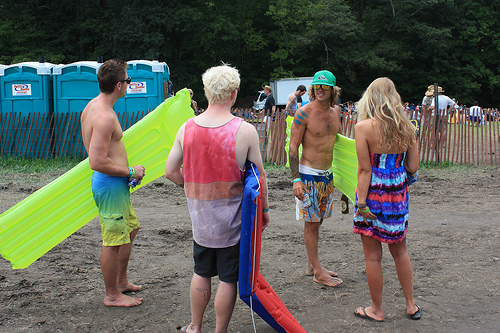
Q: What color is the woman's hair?
A: Blonde.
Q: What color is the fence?
A: Brown.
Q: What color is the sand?
A: Brown.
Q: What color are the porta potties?
A: Blue.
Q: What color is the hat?
A: Green.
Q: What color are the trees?
A: Green.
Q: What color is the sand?
A: Brown.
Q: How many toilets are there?
A: Three.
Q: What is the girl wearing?
A: A dress.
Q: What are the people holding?
A: Pool toys.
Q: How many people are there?
A: More than five.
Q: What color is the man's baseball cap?
A: Green.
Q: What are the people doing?
A: Talking.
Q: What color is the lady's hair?
A: Blonde.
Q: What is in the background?
A: Trees.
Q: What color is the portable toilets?
A: Blue.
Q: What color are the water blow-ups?
A: Yellow.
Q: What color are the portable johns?
A: Blue.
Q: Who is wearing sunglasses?
A: The men.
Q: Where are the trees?
A: Behind the fence.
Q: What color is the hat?
A: Teal.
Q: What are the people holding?
A: Air mattresses.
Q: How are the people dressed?
A: To go to the beach.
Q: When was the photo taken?
A: During the day.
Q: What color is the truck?
A: White.